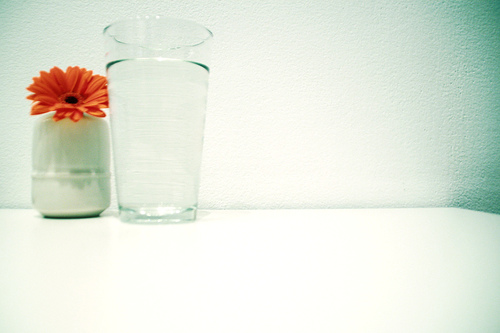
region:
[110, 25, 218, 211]
this is a glass of water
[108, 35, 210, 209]
the glass is almost full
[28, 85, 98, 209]
this is a flower vase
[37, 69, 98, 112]
the flower is orange in color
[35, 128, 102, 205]
the vase is white in color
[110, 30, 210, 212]
the glass is big in size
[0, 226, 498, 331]
the table is white in color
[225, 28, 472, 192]
the wall is white in color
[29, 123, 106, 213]
the vase is short in size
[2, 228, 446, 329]
the table is clean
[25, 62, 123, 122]
flower is red and vibrant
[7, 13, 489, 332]
The walls are white.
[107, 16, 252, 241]
A clear glass is on the table.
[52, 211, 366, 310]
The table is white.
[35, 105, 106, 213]
A flower vase is on the table.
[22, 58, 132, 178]
A orange flower is in the vase.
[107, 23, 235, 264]
The glass has water in it.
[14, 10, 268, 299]
The vase is shorter than the glass.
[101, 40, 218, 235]
The glass is taller than the vase.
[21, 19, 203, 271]
The vase and glass are together.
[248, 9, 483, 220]
The white wall is textured.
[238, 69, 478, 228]
wall is white and bright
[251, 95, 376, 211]
wall is white and bright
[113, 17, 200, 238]
glass of water is clear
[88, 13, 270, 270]
glass of water is clear